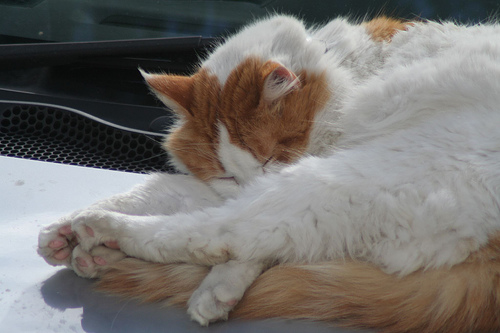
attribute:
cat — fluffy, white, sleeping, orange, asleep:
[33, 7, 500, 330]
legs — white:
[73, 168, 356, 270]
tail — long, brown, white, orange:
[93, 247, 500, 331]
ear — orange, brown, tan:
[135, 66, 194, 114]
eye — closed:
[259, 138, 282, 165]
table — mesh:
[1, 144, 499, 332]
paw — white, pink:
[36, 218, 79, 269]